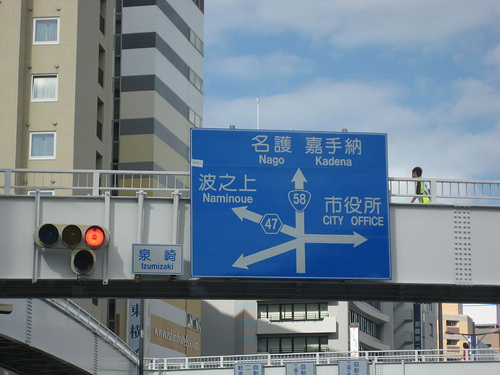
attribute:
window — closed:
[32, 17, 60, 47]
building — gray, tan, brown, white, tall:
[0, 1, 207, 357]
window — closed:
[32, 73, 59, 101]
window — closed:
[29, 130, 57, 158]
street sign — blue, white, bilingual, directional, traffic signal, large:
[192, 128, 391, 281]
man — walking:
[407, 167, 433, 205]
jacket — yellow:
[417, 183, 432, 205]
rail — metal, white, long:
[1, 165, 499, 206]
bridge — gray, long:
[3, 166, 495, 370]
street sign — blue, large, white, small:
[131, 243, 185, 279]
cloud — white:
[206, 4, 494, 52]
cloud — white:
[207, 47, 312, 84]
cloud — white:
[201, 75, 496, 203]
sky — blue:
[203, 2, 499, 205]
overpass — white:
[1, 165, 493, 298]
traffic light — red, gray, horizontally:
[35, 224, 108, 274]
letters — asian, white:
[254, 153, 287, 168]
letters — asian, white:
[313, 155, 353, 171]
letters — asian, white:
[201, 192, 255, 205]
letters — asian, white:
[319, 214, 382, 228]